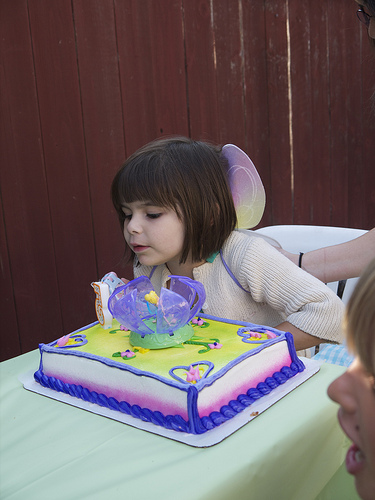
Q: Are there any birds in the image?
A: No, there are no birds.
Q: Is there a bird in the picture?
A: No, there are no birds.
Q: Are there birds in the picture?
A: No, there are no birds.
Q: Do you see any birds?
A: No, there are no birds.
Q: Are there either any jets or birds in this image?
A: No, there are no birds or jets.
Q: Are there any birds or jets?
A: No, there are no birds or jets.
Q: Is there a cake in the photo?
A: Yes, there is a cake.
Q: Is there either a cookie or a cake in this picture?
A: Yes, there is a cake.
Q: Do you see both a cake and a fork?
A: No, there is a cake but no forks.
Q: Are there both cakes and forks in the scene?
A: No, there is a cake but no forks.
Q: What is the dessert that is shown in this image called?
A: The dessert is a cake.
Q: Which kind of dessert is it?
A: The dessert is a cake.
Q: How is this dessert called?
A: This is a cake.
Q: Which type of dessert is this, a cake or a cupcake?
A: This is a cake.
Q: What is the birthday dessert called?
A: The dessert is a cake.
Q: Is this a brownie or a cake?
A: This is a cake.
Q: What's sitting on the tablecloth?
A: The cake is sitting on the tablecloth.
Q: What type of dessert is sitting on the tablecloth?
A: The dessert is a cake.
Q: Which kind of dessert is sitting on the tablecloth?
A: The dessert is a cake.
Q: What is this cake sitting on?
A: The cake is sitting on the tablecloth.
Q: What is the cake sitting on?
A: The cake is sitting on the tablecloth.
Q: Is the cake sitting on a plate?
A: No, the cake is sitting on the tablecloth.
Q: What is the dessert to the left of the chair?
A: The dessert is a cake.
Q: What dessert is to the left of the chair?
A: The dessert is a cake.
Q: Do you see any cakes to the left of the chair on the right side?
A: Yes, there is a cake to the left of the chair.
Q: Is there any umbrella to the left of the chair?
A: No, there is a cake to the left of the chair.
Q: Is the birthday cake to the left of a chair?
A: Yes, the cake is to the left of a chair.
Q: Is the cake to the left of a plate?
A: No, the cake is to the left of a chair.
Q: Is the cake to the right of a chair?
A: No, the cake is to the left of a chair.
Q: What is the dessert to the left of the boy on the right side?
A: The dessert is a cake.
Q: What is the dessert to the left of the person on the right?
A: The dessert is a cake.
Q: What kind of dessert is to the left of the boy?
A: The dessert is a cake.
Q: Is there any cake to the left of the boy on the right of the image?
A: Yes, there is a cake to the left of the boy.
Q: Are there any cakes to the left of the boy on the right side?
A: Yes, there is a cake to the left of the boy.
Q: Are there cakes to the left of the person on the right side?
A: Yes, there is a cake to the left of the boy.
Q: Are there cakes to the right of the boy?
A: No, the cake is to the left of the boy.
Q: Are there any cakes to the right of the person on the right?
A: No, the cake is to the left of the boy.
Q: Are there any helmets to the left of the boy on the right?
A: No, there is a cake to the left of the boy.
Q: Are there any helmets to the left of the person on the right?
A: No, there is a cake to the left of the boy.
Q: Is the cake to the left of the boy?
A: Yes, the cake is to the left of the boy.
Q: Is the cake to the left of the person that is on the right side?
A: Yes, the cake is to the left of the boy.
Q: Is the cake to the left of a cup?
A: No, the cake is to the left of the boy.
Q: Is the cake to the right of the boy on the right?
A: No, the cake is to the left of the boy.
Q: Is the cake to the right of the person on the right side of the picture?
A: No, the cake is to the left of the boy.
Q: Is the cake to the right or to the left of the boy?
A: The cake is to the left of the boy.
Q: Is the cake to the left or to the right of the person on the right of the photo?
A: The cake is to the left of the boy.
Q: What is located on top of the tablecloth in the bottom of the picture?
A: The cake is on top of the tablecloth.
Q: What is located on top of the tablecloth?
A: The cake is on top of the tablecloth.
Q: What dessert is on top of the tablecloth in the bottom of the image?
A: The dessert is a cake.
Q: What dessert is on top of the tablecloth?
A: The dessert is a cake.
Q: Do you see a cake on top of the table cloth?
A: Yes, there is a cake on top of the table cloth.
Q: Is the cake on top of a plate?
A: No, the cake is on top of the tablecloth.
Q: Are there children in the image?
A: Yes, there is a child.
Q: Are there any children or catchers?
A: Yes, there is a child.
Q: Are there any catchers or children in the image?
A: Yes, there is a child.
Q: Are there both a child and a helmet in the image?
A: No, there is a child but no helmets.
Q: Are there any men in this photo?
A: No, there are no men.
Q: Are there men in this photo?
A: No, there are no men.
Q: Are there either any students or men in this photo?
A: No, there are no men or students.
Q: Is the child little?
A: Yes, the child is little.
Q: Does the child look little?
A: Yes, the child is little.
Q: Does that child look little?
A: Yes, the child is little.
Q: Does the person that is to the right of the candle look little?
A: Yes, the child is little.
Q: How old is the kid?
A: The kid is little.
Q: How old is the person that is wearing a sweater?
A: The kid is little.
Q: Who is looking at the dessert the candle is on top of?
A: The kid is looking at the cake.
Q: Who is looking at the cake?
A: The kid is looking at the cake.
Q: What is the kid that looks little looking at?
A: The kid is looking at the cake.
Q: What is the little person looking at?
A: The kid is looking at the cake.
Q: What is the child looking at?
A: The kid is looking at the cake.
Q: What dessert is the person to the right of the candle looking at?
A: The child is looking at the cake.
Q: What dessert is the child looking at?
A: The child is looking at the cake.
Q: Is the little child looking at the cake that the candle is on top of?
A: Yes, the kid is looking at the cake.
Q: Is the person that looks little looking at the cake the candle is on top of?
A: Yes, the kid is looking at the cake.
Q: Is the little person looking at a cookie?
A: No, the kid is looking at the cake.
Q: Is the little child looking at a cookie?
A: No, the kid is looking at the cake.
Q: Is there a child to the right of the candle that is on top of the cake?
A: Yes, there is a child to the right of the candle.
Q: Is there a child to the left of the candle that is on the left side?
A: No, the child is to the right of the candle.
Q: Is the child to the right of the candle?
A: Yes, the child is to the right of the candle.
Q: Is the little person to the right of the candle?
A: Yes, the child is to the right of the candle.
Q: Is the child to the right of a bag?
A: No, the child is to the right of the candle.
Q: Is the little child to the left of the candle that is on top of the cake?
A: No, the kid is to the right of the candle.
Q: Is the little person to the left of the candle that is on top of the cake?
A: No, the kid is to the right of the candle.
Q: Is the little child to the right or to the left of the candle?
A: The kid is to the right of the candle.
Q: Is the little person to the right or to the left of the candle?
A: The kid is to the right of the candle.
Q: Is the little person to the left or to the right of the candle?
A: The kid is to the right of the candle.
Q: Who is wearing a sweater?
A: The child is wearing a sweater.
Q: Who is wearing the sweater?
A: The child is wearing a sweater.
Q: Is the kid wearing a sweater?
A: Yes, the kid is wearing a sweater.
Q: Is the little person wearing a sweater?
A: Yes, the kid is wearing a sweater.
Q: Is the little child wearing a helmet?
A: No, the child is wearing a sweater.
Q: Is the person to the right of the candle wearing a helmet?
A: No, the child is wearing a sweater.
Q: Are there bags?
A: No, there are no bags.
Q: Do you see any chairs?
A: Yes, there is a chair.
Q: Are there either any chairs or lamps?
A: Yes, there is a chair.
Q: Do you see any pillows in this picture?
A: No, there are no pillows.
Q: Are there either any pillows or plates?
A: No, there are no pillows or plates.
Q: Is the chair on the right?
A: Yes, the chair is on the right of the image.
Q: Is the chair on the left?
A: No, the chair is on the right of the image.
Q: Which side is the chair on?
A: The chair is on the right of the image.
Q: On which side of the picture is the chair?
A: The chair is on the right of the image.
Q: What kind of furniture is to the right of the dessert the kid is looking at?
A: The piece of furniture is a chair.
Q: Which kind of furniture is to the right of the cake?
A: The piece of furniture is a chair.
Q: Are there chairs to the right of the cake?
A: Yes, there is a chair to the right of the cake.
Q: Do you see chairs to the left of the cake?
A: No, the chair is to the right of the cake.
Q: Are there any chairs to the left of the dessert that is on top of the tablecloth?
A: No, the chair is to the right of the cake.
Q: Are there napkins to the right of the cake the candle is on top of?
A: No, there is a chair to the right of the cake.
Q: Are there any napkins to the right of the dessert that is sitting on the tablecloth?
A: No, there is a chair to the right of the cake.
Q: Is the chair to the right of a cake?
A: Yes, the chair is to the right of a cake.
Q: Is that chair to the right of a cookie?
A: No, the chair is to the right of a cake.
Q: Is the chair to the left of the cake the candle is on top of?
A: No, the chair is to the right of the cake.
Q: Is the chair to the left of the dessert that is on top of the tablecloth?
A: No, the chair is to the right of the cake.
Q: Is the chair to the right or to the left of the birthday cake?
A: The chair is to the right of the cake.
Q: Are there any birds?
A: No, there are no birds.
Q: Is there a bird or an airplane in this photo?
A: No, there are no birds or airplanes.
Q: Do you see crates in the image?
A: No, there are no crates.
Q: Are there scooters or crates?
A: No, there are no crates or scooters.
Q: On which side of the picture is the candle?
A: The candle is on the left of the image.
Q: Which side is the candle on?
A: The candle is on the left of the image.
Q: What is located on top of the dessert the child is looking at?
A: The candle is on top of the cake.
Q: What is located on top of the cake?
A: The candle is on top of the cake.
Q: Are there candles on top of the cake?
A: Yes, there is a candle on top of the cake.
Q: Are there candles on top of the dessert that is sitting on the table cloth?
A: Yes, there is a candle on top of the cake.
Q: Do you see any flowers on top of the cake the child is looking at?
A: No, there is a candle on top of the cake.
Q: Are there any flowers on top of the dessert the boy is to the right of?
A: No, there is a candle on top of the cake.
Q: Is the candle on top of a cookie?
A: No, the candle is on top of a cake.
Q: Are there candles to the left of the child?
A: Yes, there is a candle to the left of the child.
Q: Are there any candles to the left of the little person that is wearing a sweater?
A: Yes, there is a candle to the left of the child.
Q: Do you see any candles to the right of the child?
A: No, the candle is to the left of the child.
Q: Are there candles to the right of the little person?
A: No, the candle is to the left of the child.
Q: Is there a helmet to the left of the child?
A: No, there is a candle to the left of the child.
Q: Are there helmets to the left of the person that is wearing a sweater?
A: No, there is a candle to the left of the child.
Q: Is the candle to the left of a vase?
A: No, the candle is to the left of the kid.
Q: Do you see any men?
A: No, there are no men.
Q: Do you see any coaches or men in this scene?
A: No, there are no men or coaches.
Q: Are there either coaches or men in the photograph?
A: No, there are no men or coaches.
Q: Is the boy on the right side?
A: Yes, the boy is on the right of the image.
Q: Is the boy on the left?
A: No, the boy is on the right of the image.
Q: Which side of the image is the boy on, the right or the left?
A: The boy is on the right of the image.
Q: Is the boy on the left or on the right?
A: The boy is on the right of the image.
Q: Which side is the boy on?
A: The boy is on the right of the image.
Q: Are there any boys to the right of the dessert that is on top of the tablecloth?
A: Yes, there is a boy to the right of the cake.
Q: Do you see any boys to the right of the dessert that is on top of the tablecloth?
A: Yes, there is a boy to the right of the cake.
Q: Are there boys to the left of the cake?
A: No, the boy is to the right of the cake.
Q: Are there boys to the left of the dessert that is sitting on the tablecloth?
A: No, the boy is to the right of the cake.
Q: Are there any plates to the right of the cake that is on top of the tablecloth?
A: No, there is a boy to the right of the cake.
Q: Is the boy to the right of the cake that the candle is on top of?
A: Yes, the boy is to the right of the cake.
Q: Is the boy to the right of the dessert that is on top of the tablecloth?
A: Yes, the boy is to the right of the cake.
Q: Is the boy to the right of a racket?
A: No, the boy is to the right of the cake.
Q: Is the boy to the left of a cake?
A: No, the boy is to the right of a cake.